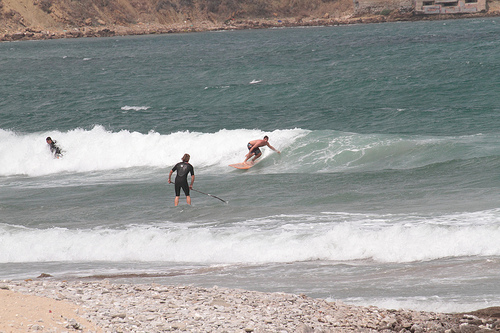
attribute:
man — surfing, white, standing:
[235, 132, 279, 161]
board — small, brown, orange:
[230, 160, 258, 172]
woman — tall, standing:
[162, 148, 203, 207]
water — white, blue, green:
[1, 20, 486, 304]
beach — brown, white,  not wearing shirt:
[3, 253, 481, 332]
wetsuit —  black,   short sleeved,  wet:
[172, 165, 195, 198]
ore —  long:
[174, 180, 228, 203]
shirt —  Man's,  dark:
[43, 142, 61, 154]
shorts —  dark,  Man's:
[246, 138, 260, 163]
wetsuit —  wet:
[169, 159, 192, 195]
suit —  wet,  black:
[169, 162, 194, 195]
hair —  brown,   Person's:
[183, 152, 191, 162]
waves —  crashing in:
[6, 114, 496, 177]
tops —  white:
[70, 129, 170, 167]